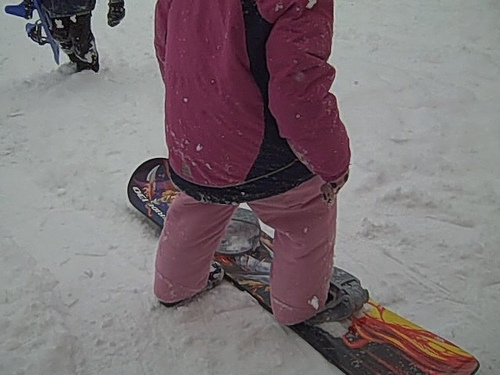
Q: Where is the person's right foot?
A: One the snowboard.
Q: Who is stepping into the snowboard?
A: The person.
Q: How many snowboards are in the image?
A: One.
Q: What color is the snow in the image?
A: White.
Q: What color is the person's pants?
A: Pink.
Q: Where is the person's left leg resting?
A: On the snow.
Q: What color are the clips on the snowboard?
A: Gray.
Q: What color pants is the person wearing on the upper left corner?
A: Black.